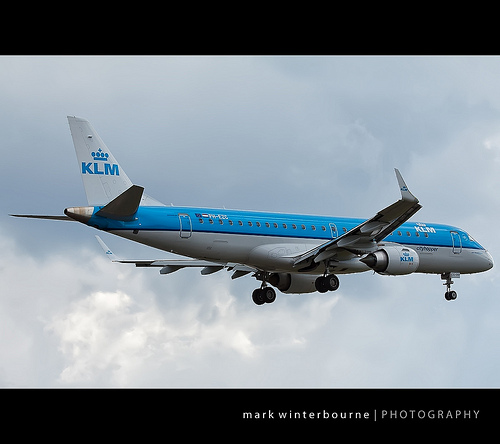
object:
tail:
[65, 111, 171, 210]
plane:
[7, 113, 497, 310]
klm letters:
[79, 159, 95, 178]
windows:
[292, 218, 300, 231]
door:
[174, 210, 194, 243]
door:
[327, 220, 342, 240]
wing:
[94, 225, 240, 283]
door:
[450, 228, 466, 257]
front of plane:
[418, 216, 499, 304]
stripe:
[102, 222, 487, 253]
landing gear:
[314, 274, 327, 298]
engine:
[360, 242, 420, 278]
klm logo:
[397, 254, 420, 263]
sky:
[1, 55, 499, 388]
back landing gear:
[258, 285, 279, 303]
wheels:
[260, 284, 276, 304]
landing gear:
[443, 292, 450, 302]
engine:
[261, 269, 328, 296]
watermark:
[240, 404, 371, 424]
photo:
[2, 1, 500, 442]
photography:
[380, 404, 480, 421]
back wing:
[92, 180, 146, 221]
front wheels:
[447, 288, 458, 301]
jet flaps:
[281, 164, 425, 278]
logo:
[90, 142, 110, 161]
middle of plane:
[172, 158, 421, 313]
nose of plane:
[456, 221, 499, 280]